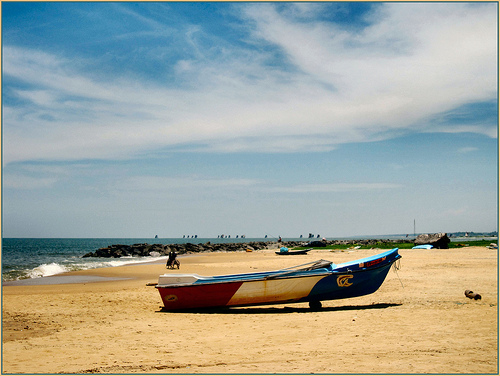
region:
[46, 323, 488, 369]
The beach sand is beige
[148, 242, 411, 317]
A boat sitting on the beach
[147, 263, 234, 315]
The red end of the boat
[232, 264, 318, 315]
The white part in the middle of the boat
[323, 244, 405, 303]
The blue and front end of the boat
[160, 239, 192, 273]
A person sitting on the beach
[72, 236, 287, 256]
Large boulder rocks in the water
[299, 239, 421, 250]
The grass is very green and cut short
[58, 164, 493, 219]
The sky is blue and white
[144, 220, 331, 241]
Sailboats far in the ocean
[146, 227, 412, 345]
canoe on the sand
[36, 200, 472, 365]
canoe near the beach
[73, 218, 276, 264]
rocks near the beach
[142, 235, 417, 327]
red, blue , and white canoe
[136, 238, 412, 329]
canoe with dirt on it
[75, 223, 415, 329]
canoe near rocks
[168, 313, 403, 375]
brown sand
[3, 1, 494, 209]
white clouds in the sky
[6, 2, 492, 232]
clear blue skies with clouds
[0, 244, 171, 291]
small waves near shore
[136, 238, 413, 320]
boat on the beach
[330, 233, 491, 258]
grass on the beach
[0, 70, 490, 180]
cloud in the sky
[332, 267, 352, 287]
logo on the boat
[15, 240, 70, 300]
wave in the ocean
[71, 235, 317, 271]
jetty on the shore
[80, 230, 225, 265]
rocks in the jetty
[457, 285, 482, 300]
log on the beach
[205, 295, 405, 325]
shadow of the boat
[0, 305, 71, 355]
wet sand on the beach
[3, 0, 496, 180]
a large white cloud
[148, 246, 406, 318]
a colorful boat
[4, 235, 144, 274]
blue ocean water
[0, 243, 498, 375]
brown sandy beach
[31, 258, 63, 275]
white water waves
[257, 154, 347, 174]
part of a blue sky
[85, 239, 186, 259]
a large area of rocks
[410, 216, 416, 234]
a small gray pole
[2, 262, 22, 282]
a small section of green moss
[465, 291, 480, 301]
a small brown log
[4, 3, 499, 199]
Mix of sunshine and clouds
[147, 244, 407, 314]
Colorful boat on the beach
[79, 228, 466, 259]
Rocks going out into the water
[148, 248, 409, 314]
Red, white and blue boat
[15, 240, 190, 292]
Waves washing ashore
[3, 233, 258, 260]
Water is very calm today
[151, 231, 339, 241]
Sailboats out in the distance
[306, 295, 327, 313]
Keel of the boat resting on something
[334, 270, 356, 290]
Logo on the front of the boat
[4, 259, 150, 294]
Damp sand on the beach where the waves washed up